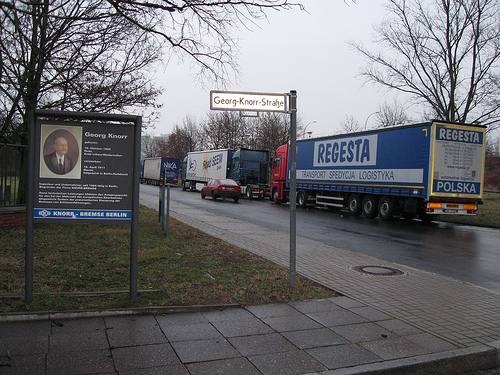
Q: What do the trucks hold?
A: Cargo.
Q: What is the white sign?
A: Street name.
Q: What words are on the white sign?
A: Georg-Knorr-Stralye.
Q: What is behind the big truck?
A: Trees.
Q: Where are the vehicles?
A: On the road.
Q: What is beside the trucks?
A: Car.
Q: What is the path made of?
A: Stones.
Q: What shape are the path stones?
A: Square.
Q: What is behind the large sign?
A: Grass.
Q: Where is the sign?
A: Beside the walkway.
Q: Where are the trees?
A: Behind the trucks.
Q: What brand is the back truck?
A: Regesta.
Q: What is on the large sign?
A: Face.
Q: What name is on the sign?
A: Georg Knorr.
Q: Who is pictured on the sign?
A: George Knorr.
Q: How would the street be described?
A: Wet, black asphalt.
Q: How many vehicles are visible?
A: Five.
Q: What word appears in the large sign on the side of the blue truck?
A: Regesta.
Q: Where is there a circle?
A: In the sidewalk.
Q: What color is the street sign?
A: White.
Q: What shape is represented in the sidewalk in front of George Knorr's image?
A: Squares.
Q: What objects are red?
A: The car and the cab of the blue tractor trailer.